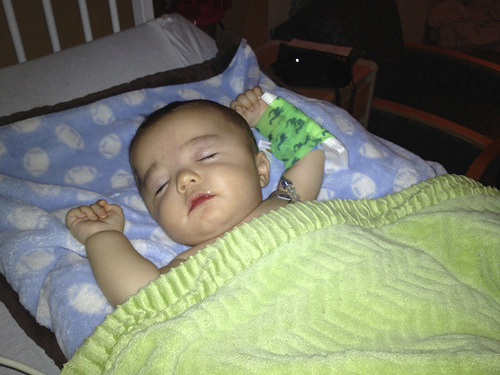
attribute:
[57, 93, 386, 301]
baby — sleeping, laying down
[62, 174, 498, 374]
blanket — light green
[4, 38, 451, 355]
blanket — football patterned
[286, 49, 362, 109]
telephone — corded, black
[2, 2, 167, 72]
headboard — metal, white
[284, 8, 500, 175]
armchair — dark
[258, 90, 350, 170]
cast — design